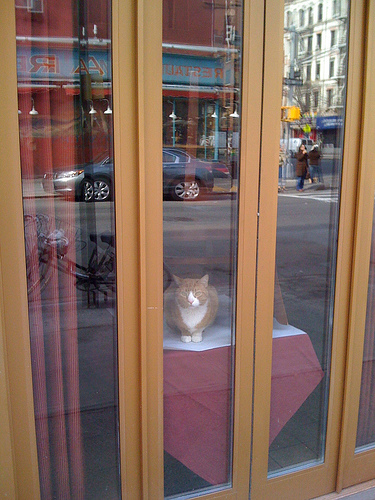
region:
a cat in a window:
[166, 266, 227, 344]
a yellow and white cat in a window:
[165, 254, 226, 358]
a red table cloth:
[165, 337, 320, 484]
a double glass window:
[150, 142, 350, 489]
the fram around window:
[110, 139, 168, 481]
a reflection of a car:
[46, 147, 216, 205]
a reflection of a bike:
[7, 205, 155, 312]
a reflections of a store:
[20, 36, 240, 184]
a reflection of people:
[292, 136, 328, 201]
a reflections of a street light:
[274, 94, 305, 189]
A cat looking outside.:
[162, 272, 219, 342]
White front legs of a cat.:
[180, 330, 202, 343]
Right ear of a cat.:
[169, 270, 180, 281]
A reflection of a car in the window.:
[42, 142, 216, 203]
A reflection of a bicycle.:
[25, 215, 171, 304]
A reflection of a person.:
[292, 143, 308, 191]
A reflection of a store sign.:
[20, 49, 236, 94]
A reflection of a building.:
[282, 1, 352, 160]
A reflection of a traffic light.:
[282, 104, 301, 124]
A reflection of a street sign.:
[283, 76, 302, 85]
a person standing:
[293, 142, 311, 188]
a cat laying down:
[167, 277, 222, 336]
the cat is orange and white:
[168, 272, 218, 340]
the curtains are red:
[33, 297, 85, 490]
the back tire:
[173, 173, 212, 199]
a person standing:
[311, 144, 326, 186]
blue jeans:
[293, 172, 304, 190]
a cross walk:
[311, 186, 332, 201]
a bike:
[76, 257, 115, 302]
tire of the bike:
[25, 255, 56, 299]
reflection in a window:
[18, 213, 118, 316]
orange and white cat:
[151, 275, 234, 356]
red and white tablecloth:
[161, 322, 319, 434]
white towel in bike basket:
[35, 204, 98, 294]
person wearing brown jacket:
[273, 136, 327, 211]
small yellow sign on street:
[273, 99, 313, 136]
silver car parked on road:
[3, 129, 239, 244]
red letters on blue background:
[4, 52, 237, 98]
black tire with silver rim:
[152, 181, 206, 214]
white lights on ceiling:
[3, 97, 243, 135]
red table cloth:
[182, 399, 212, 450]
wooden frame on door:
[130, 420, 155, 469]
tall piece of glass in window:
[277, 289, 319, 413]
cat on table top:
[169, 269, 216, 339]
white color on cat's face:
[183, 292, 207, 310]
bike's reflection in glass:
[32, 219, 107, 291]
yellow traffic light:
[285, 100, 305, 130]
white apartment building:
[300, 8, 336, 102]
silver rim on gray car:
[170, 175, 219, 213]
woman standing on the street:
[292, 140, 311, 199]